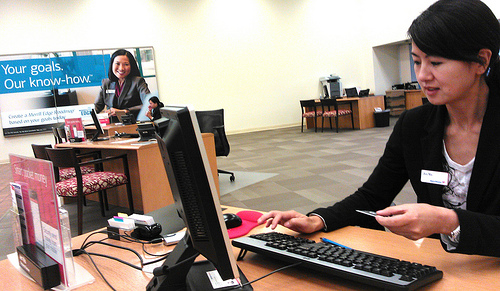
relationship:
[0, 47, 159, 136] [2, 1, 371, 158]
sign hanging on wall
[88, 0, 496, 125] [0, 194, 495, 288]
women at desk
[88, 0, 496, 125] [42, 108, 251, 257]
women at desk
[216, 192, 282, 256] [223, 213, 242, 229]
mousepad under black mouse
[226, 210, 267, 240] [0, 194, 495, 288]
mousepad on desk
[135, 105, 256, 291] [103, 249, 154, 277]
computer on desk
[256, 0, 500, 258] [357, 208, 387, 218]
lady holding credit card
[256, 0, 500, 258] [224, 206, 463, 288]
lady typing keyboard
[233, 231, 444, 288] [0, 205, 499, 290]
keyboard on desk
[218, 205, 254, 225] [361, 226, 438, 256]
black mouse on table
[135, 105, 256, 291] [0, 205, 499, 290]
computer on desk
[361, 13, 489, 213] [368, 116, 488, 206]
lady wearing jacket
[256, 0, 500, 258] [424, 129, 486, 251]
lady wearing top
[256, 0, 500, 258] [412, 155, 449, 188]
lady wearing badge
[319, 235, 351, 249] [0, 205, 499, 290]
pen on desk